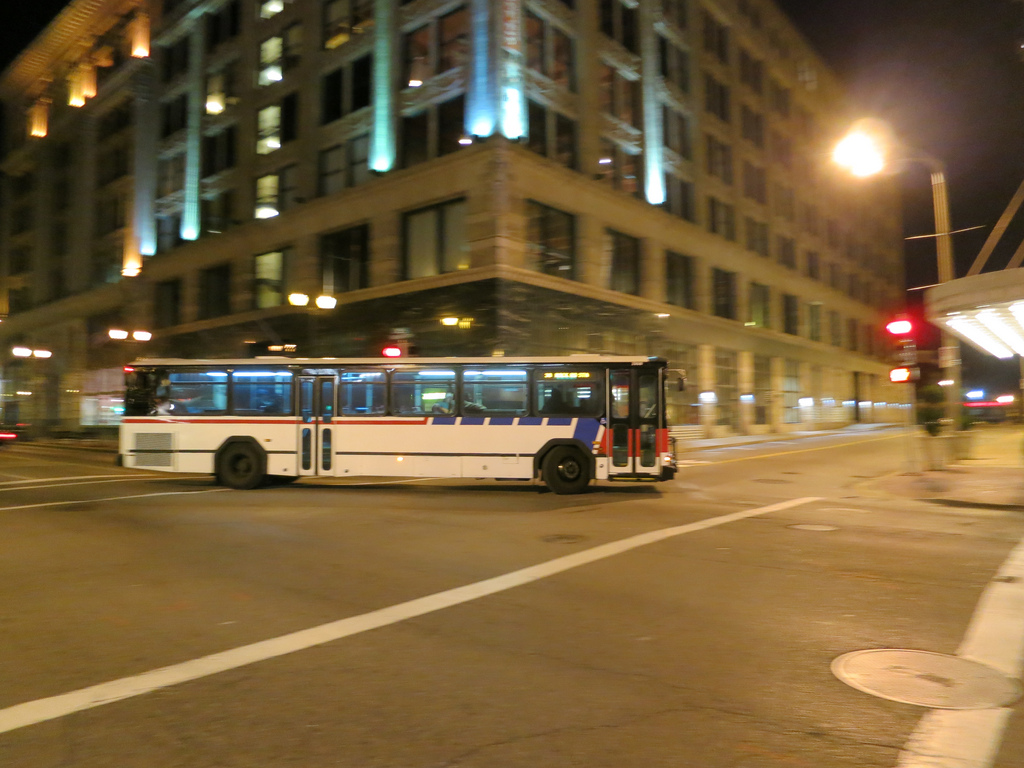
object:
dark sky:
[914, 4, 1018, 154]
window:
[427, 0, 495, 90]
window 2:
[336, 51, 383, 109]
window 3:
[395, 187, 478, 280]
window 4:
[250, 26, 296, 97]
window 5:
[518, 188, 587, 284]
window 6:
[592, 48, 657, 140]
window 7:
[594, 125, 655, 203]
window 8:
[659, 96, 698, 167]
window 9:
[744, 273, 777, 331]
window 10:
[194, 186, 246, 242]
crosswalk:
[6, 474, 1019, 762]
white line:
[6, 484, 814, 742]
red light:
[882, 314, 914, 360]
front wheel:
[539, 443, 594, 497]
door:
[608, 364, 657, 473]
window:
[399, 209, 445, 283]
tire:
[213, 440, 271, 488]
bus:
[113, 349, 701, 490]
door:
[288, 354, 342, 479]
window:
[528, 373, 596, 416]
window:
[455, 357, 529, 418]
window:
[389, 364, 454, 415]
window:
[343, 354, 386, 412]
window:
[232, 362, 293, 413]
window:
[515, 84, 558, 149]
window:
[521, 7, 548, 76]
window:
[247, 100, 282, 157]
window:
[339, 219, 382, 288]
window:
[200, 267, 233, 312]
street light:
[819, 115, 924, 191]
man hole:
[826, 649, 1009, 714]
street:
[0, 405, 1022, 764]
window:
[747, 276, 774, 329]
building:
[0, 5, 925, 432]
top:
[830, 629, 1017, 718]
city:
[17, 27, 1016, 760]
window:
[302, 53, 382, 112]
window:
[389, 9, 428, 91]